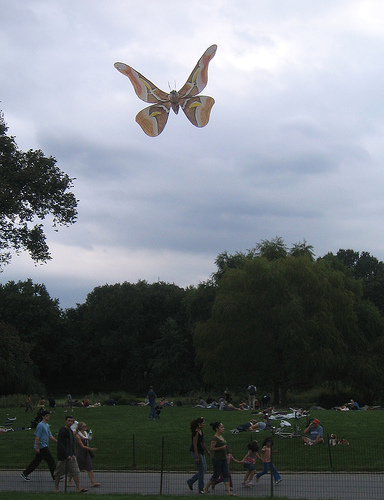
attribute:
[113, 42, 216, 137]
kite — butterfly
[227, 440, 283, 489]
girls — young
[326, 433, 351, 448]
dog — brown, white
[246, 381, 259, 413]
people — under a tree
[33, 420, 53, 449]
shirt — blue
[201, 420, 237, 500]
people — walking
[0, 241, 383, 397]
trees — green, big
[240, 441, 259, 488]
kids — holding hands, walking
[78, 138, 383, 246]
sky — gray, cloudy, grey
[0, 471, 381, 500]
walkway — grey, concrete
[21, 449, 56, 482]
pants — black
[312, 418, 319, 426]
hat — red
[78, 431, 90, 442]
ring — white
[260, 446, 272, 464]
shirts — orange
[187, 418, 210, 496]
two women — walking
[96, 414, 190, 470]
grass — green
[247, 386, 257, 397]
backpack — black